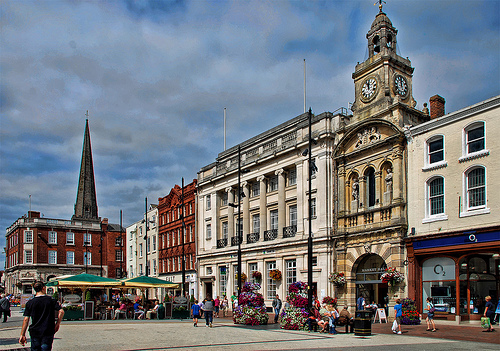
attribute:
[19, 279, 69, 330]
black tshirt — short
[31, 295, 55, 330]
shirt — black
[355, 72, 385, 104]
clock — large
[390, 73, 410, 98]
clock — large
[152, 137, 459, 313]
buildings — large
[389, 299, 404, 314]
shirt — blue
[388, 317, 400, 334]
bag — white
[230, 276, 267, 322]
flowers — red, green, purple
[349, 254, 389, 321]
door — arching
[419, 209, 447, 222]
window pane — white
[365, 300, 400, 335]
sign — white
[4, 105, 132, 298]
building — tapering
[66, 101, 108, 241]
gray spire — tall, dark gray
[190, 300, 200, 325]
boy — young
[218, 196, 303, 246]
windows — glass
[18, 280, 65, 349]
person — male, walking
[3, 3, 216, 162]
sky — blue, cloudy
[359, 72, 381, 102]
clock — white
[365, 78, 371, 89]
hands — black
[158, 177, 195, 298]
building — brick, large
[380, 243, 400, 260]
brick — brown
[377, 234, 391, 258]
brick — tan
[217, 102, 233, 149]
mast — flag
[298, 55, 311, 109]
mast — flag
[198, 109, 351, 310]
building — tall, white